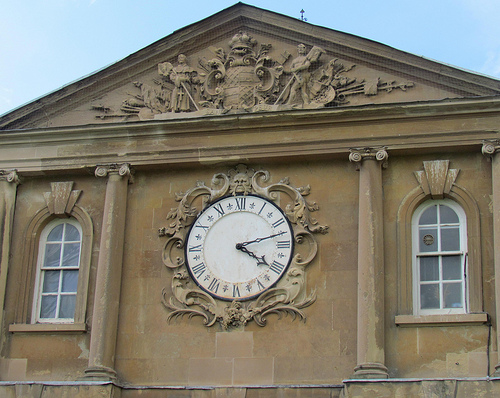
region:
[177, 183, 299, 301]
clock with white face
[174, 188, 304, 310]
clock with black hands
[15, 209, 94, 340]
window on a building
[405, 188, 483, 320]
window on a building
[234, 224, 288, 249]
black hand on a clock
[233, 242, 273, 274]
black hand on a clock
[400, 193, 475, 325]
window with white frame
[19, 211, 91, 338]
window with white frame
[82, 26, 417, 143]
intricate design on building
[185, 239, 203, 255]
black number on a clock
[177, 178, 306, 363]
a clock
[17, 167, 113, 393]
a window on the building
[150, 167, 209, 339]
masonry work on the building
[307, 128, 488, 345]
column next to the window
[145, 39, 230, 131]
statue on the building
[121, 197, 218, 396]
limestone blocks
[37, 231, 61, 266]
window panes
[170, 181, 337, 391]
white face clock on the building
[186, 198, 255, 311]
roman numerals on the clock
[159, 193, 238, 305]
decorative stone work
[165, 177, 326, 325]
The clock is on the front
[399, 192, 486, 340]
The window is on the front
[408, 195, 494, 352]
The window is white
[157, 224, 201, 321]
There is art surrounding the clock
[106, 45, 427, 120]
A scene is on top of the building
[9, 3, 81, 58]
The sky is blue with no clouds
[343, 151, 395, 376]
A concrete pedestal is on the front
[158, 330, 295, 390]
The front is made of bricks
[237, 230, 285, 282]
There are hands on the clock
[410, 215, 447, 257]
A person is looking out the window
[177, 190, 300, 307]
clock with black rim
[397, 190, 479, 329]
window with round top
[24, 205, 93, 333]
window with round top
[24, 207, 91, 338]
window with white trim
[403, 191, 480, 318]
window with white trim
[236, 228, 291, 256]
black metal clock hand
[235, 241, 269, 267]
black metal clock hand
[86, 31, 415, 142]
intricate design on a building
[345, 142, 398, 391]
carved pillar on a building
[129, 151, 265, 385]
a clock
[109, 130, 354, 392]
a clock